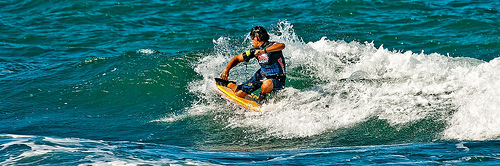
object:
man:
[245, 23, 284, 85]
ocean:
[9, 8, 490, 165]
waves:
[29, 52, 162, 122]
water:
[316, 27, 499, 139]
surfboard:
[209, 71, 255, 123]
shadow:
[200, 121, 291, 158]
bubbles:
[219, 117, 264, 157]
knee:
[260, 85, 268, 91]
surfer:
[237, 11, 292, 103]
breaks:
[335, 35, 364, 50]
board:
[213, 80, 257, 119]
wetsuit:
[251, 46, 282, 84]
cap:
[371, 46, 400, 67]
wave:
[296, 22, 473, 111]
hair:
[243, 22, 272, 39]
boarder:
[240, 20, 285, 84]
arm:
[254, 39, 302, 72]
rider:
[237, 15, 279, 91]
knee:
[242, 74, 249, 103]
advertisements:
[255, 53, 272, 72]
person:
[247, 21, 298, 92]